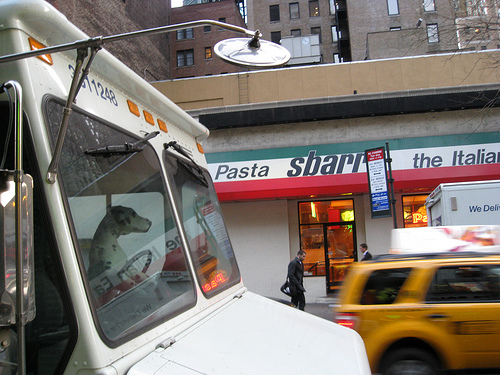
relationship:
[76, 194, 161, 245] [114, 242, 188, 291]
dog behind wheel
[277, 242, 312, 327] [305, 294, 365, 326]
man at sidewalk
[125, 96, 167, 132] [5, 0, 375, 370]
reflectors on truck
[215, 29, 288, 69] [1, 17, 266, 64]
mirror on pole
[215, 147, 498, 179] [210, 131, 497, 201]
words on awning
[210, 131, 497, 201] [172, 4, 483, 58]
awning on buildings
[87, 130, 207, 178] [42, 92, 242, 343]
wipers on windshield